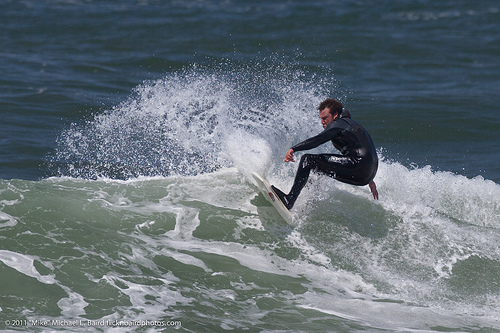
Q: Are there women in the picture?
A: No, there are no women.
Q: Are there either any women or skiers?
A: No, there are no women or skiers.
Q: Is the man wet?
A: Yes, the man is wet.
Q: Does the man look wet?
A: Yes, the man is wet.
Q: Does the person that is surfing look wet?
A: Yes, the man is wet.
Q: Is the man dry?
A: No, the man is wet.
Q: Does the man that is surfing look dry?
A: No, the man is wet.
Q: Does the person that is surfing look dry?
A: No, the man is wet.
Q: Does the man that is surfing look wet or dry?
A: The man is wet.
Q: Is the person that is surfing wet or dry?
A: The man is wet.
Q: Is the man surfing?
A: Yes, the man is surfing.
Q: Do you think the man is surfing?
A: Yes, the man is surfing.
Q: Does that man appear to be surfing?
A: Yes, the man is surfing.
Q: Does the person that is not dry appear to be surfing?
A: Yes, the man is surfing.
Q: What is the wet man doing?
A: The man is surfing.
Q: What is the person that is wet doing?
A: The man is surfing.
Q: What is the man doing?
A: The man is surfing.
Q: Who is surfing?
A: The man is surfing.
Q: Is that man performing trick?
A: No, the man is surfing.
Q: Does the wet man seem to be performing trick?
A: No, the man is surfing.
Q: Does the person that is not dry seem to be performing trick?
A: No, the man is surfing.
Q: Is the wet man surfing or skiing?
A: The man is surfing.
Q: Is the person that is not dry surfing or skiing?
A: The man is surfing.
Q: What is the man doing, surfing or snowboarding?
A: The man is surfing.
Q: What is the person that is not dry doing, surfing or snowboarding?
A: The man is surfing.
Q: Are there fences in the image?
A: No, there are no fences.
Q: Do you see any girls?
A: No, there are no girls.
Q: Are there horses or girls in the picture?
A: No, there are no girls or horses.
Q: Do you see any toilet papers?
A: No, there are no toilet papers.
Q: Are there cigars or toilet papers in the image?
A: No, there are no toilet papers or cigars.